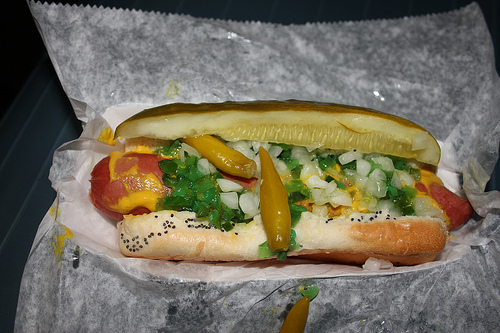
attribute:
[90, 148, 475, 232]
hotdog — wiener, cooked, end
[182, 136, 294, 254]
pickles — small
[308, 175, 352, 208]
onions — white, chopped, bit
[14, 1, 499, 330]
paper — white, waxed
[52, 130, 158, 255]
mustard — golden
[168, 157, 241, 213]
relish — green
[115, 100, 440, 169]
pickle — long, spear, green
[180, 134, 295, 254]
peppers — yellow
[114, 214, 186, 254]
seeds — cluster, black, pale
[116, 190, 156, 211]
cheese — yellow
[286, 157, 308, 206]
vegetable — green